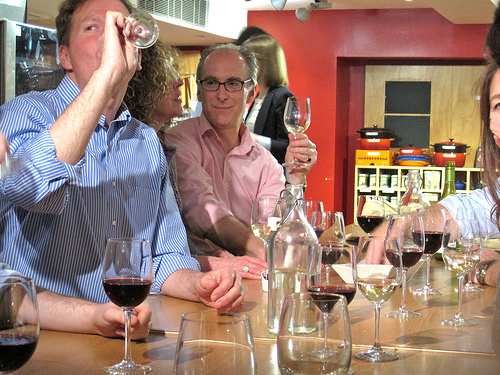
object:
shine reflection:
[283, 98, 311, 134]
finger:
[285, 132, 321, 171]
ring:
[307, 158, 312, 162]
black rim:
[198, 75, 253, 92]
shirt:
[163, 112, 286, 240]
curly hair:
[124, 45, 180, 130]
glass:
[122, 9, 159, 50]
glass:
[0, 271, 42, 375]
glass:
[173, 310, 258, 374]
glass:
[351, 230, 404, 365]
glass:
[382, 211, 427, 318]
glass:
[440, 216, 486, 327]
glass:
[410, 203, 451, 298]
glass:
[355, 196, 385, 234]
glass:
[250, 195, 282, 285]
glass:
[267, 184, 323, 339]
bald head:
[204, 46, 246, 68]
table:
[0, 215, 496, 375]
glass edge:
[285, 290, 344, 303]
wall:
[313, 12, 471, 123]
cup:
[100, 237, 154, 375]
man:
[2, 0, 243, 338]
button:
[112, 182, 117, 188]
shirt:
[1, 71, 199, 304]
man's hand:
[195, 267, 246, 317]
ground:
[373, 137, 413, 169]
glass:
[307, 244, 356, 358]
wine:
[101, 279, 151, 309]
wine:
[307, 283, 356, 313]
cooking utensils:
[356, 124, 472, 168]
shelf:
[349, 161, 484, 224]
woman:
[237, 26, 290, 88]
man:
[163, 40, 317, 264]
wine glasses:
[298, 191, 450, 360]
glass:
[308, 211, 347, 322]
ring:
[243, 266, 250, 273]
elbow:
[0, 150, 83, 216]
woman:
[364, 51, 500, 288]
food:
[346, 259, 386, 263]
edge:
[347, 89, 364, 133]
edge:
[110, 237, 150, 243]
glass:
[275, 291, 354, 371]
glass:
[280, 95, 309, 168]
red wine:
[102, 276, 152, 308]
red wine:
[410, 230, 446, 256]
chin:
[214, 119, 232, 129]